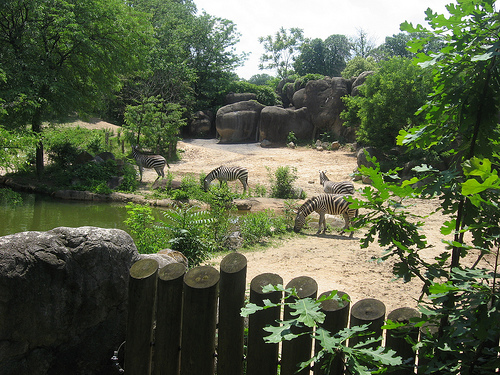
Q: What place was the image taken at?
A: It was taken at the zoo.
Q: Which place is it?
A: It is a zoo.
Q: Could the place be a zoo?
A: Yes, it is a zoo.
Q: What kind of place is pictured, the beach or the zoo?
A: It is the zoo.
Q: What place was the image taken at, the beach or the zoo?
A: It was taken at the zoo.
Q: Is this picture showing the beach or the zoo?
A: It is showing the zoo.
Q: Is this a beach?
A: No, it is a zoo.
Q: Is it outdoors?
A: Yes, it is outdoors.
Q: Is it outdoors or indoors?
A: It is outdoors.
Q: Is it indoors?
A: No, it is outdoors.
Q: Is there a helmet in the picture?
A: No, there are no helmets.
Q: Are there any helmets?
A: No, there are no helmets.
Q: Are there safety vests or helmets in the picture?
A: No, there are no helmets or safety vests.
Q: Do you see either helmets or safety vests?
A: No, there are no helmets or safety vests.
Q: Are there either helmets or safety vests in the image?
A: No, there are no helmets or safety vests.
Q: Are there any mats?
A: No, there are no mats.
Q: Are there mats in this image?
A: No, there are no mats.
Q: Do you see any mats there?
A: No, there are no mats.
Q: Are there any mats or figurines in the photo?
A: No, there are no mats or figurines.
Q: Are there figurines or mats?
A: No, there are no mats or figurines.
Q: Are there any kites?
A: No, there are no kites.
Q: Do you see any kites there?
A: No, there are no kites.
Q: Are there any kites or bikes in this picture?
A: No, there are no kites or bikes.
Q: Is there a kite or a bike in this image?
A: No, there are no kites or bikes.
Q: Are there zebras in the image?
A: Yes, there is a zebra.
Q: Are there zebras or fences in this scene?
A: Yes, there is a zebra.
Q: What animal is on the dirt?
A: The zebra is on the dirt.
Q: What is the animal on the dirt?
A: The animal is a zebra.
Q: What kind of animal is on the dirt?
A: The animal is a zebra.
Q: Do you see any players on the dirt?
A: No, there is a zebra on the dirt.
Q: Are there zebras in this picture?
A: Yes, there is a zebra.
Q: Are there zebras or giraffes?
A: Yes, there is a zebra.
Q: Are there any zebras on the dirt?
A: Yes, there is a zebra on the dirt.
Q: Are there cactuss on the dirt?
A: No, there is a zebra on the dirt.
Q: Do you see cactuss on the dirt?
A: No, there is a zebra on the dirt.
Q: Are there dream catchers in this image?
A: No, there are no dream catchers.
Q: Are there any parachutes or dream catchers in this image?
A: No, there are no dream catchers or parachutes.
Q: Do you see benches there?
A: No, there are no benches.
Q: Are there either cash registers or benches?
A: No, there are no benches or cash registers.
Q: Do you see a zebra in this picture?
A: Yes, there is a zebra.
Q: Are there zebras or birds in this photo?
A: Yes, there is a zebra.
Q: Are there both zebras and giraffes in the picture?
A: Yes, there are both a zebra and a giraffe.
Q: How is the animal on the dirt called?
A: The animal is a zebra.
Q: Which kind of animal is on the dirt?
A: The animal is a zebra.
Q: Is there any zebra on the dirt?
A: Yes, there is a zebra on the dirt.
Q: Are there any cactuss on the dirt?
A: No, there is a zebra on the dirt.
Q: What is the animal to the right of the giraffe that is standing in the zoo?
A: The animal is a zebra.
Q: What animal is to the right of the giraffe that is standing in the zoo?
A: The animal is a zebra.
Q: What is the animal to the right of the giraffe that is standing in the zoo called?
A: The animal is a zebra.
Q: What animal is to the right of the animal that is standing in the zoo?
A: The animal is a zebra.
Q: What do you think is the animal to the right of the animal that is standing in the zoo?
A: The animal is a zebra.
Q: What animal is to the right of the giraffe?
A: The animal is a zebra.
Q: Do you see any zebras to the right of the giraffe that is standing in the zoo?
A: Yes, there is a zebra to the right of the giraffe.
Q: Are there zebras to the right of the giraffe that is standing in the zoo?
A: Yes, there is a zebra to the right of the giraffe.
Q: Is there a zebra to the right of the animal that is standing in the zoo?
A: Yes, there is a zebra to the right of the giraffe.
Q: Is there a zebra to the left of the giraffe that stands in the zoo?
A: No, the zebra is to the right of the giraffe.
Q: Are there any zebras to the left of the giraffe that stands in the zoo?
A: No, the zebra is to the right of the giraffe.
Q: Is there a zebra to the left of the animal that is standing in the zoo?
A: No, the zebra is to the right of the giraffe.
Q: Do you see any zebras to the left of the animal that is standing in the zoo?
A: No, the zebra is to the right of the giraffe.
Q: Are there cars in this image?
A: No, there are no cars.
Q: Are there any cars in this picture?
A: No, there are no cars.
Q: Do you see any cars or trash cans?
A: No, there are no cars or trash cans.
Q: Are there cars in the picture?
A: No, there are no cars.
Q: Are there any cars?
A: No, there are no cars.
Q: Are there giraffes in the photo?
A: Yes, there is a giraffe.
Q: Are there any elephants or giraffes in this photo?
A: Yes, there is a giraffe.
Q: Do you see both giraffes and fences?
A: Yes, there are both a giraffe and a fence.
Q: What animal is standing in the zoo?
A: The animal is a giraffe.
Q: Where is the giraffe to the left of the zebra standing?
A: The giraffe is standing in the zoo.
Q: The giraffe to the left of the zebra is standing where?
A: The giraffe is standing in the zoo.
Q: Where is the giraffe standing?
A: The giraffe is standing in the zoo.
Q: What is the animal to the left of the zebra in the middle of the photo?
A: The animal is a giraffe.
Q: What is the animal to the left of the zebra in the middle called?
A: The animal is a giraffe.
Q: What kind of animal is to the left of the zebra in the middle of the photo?
A: The animal is a giraffe.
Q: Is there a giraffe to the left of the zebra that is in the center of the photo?
A: Yes, there is a giraffe to the left of the zebra.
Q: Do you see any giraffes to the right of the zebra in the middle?
A: No, the giraffe is to the left of the zebra.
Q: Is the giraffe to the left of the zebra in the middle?
A: Yes, the giraffe is to the left of the zebra.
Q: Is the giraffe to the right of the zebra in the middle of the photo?
A: No, the giraffe is to the left of the zebra.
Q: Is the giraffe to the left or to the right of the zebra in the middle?
A: The giraffe is to the left of the zebra.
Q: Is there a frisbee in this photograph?
A: No, there are no frisbees.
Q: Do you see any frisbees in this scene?
A: No, there are no frisbees.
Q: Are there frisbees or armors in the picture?
A: No, there are no frisbees or armors.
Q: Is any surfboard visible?
A: No, there are no surfboards.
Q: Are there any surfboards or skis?
A: No, there are no surfboards or skis.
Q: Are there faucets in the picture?
A: No, there are no faucets.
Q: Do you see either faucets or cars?
A: No, there are no faucets or cars.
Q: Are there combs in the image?
A: No, there are no combs.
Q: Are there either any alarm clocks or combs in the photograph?
A: No, there are no combs or alarm clocks.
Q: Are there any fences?
A: Yes, there is a fence.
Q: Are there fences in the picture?
A: Yes, there is a fence.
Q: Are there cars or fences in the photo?
A: Yes, there is a fence.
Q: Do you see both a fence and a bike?
A: No, there is a fence but no bikes.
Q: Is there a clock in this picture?
A: No, there are no clocks.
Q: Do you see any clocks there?
A: No, there are no clocks.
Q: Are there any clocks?
A: No, there are no clocks.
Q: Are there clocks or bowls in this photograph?
A: No, there are no clocks or bowls.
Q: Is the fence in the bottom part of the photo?
A: Yes, the fence is in the bottom of the image.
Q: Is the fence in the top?
A: No, the fence is in the bottom of the image.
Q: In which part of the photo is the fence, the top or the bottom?
A: The fence is in the bottom of the image.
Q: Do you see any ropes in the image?
A: No, there are no ropes.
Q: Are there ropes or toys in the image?
A: No, there are no ropes or toys.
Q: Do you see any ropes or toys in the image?
A: No, there are no ropes or toys.